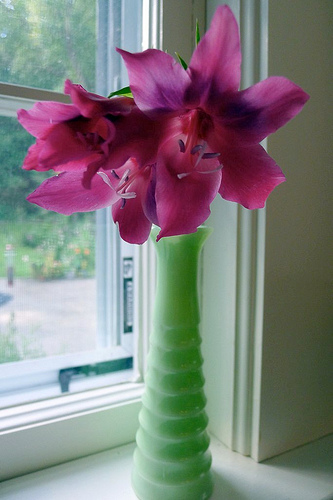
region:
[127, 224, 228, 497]
light green glass vase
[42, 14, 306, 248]
pink and purple flowers in green vase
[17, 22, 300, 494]
flowers in a vase on window sill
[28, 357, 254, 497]
window sill and window frame painted white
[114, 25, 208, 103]
green leaves behind flowers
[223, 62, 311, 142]
flower petal with pink and purple shades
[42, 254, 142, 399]
stickers on the window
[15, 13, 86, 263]
trees visible outside window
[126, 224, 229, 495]
tall think light green vase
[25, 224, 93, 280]
flowers visible outside window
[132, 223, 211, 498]
The vase is green.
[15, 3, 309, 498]
Pink flowers in a green vase.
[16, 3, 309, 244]
The flowers are pink.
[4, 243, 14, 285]
Blurry person outside the window.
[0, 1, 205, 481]
The window is shut.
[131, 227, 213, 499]
The vase is made of light green glass.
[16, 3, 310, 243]
The flowers are pink with hints of purple.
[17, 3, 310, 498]
Three flowers in a vase.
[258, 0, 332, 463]
The wall is painted white.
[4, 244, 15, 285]
A person is standing outside.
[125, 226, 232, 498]
a thin green vase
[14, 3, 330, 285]
the flower is a bright color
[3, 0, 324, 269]
the flower is pink and purple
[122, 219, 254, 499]
the vase is neon green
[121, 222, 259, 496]
the vase has ridges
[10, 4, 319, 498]
the flower is next to a window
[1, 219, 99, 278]
a lawn and some flowers outside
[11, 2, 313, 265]
the petals of the flower are pink and purple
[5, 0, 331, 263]
the flower has pink and purple petals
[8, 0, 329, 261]
there are green leaves and pink and purple petals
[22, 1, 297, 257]
Small pink flowers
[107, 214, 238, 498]
Tall green vase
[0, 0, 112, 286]
Trees outside of the window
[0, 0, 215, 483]
White trim of window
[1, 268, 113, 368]
Brown piece of sidewalk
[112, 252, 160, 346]
Black and white sticker on window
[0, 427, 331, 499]
Piece of white window ledge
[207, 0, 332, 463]
Piece of white wall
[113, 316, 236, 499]
Green ripples on vase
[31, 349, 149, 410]
Black lock on window